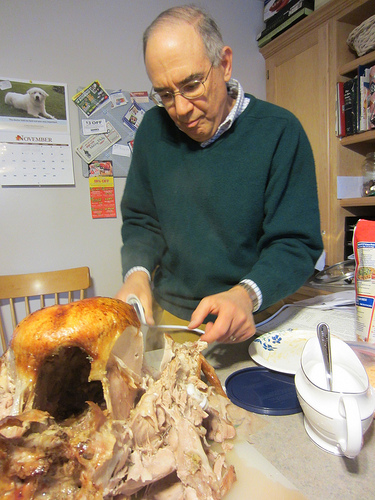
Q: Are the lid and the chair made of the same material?
A: No, the lid is made of plastic and the chair is made of wood.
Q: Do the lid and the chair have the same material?
A: No, the lid is made of plastic and the chair is made of wood.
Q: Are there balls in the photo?
A: No, there are no balls.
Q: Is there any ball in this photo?
A: No, there are no balls.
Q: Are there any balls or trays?
A: No, there are no balls or trays.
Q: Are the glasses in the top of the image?
A: Yes, the glasses are in the top of the image.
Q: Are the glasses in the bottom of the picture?
A: No, the glasses are in the top of the image.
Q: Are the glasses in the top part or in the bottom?
A: The glasses are in the top of the image.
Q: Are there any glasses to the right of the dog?
A: Yes, there are glasses to the right of the dog.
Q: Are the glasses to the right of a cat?
A: No, the glasses are to the right of the dog.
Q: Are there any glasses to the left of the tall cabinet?
A: Yes, there are glasses to the left of the cabinet.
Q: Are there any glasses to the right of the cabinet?
A: No, the glasses are to the left of the cabinet.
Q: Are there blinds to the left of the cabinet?
A: No, there are glasses to the left of the cabinet.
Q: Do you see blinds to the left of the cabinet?
A: No, there are glasses to the left of the cabinet.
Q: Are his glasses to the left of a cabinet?
A: Yes, the glasses are to the left of a cabinet.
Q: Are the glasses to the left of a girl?
A: No, the glasses are to the left of a cabinet.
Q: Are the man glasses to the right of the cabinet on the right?
A: No, the glasses are to the left of the cabinet.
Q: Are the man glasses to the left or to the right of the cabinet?
A: The glasses are to the left of the cabinet.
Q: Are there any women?
A: No, there are no women.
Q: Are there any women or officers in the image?
A: No, there are no women or officers.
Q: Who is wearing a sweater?
A: The man is wearing a sweater.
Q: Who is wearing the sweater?
A: The man is wearing a sweater.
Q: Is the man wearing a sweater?
A: Yes, the man is wearing a sweater.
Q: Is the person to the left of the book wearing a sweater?
A: Yes, the man is wearing a sweater.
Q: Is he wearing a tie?
A: No, the man is wearing a sweater.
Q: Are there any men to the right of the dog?
A: Yes, there is a man to the right of the dog.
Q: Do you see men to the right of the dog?
A: Yes, there is a man to the right of the dog.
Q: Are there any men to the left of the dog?
A: No, the man is to the right of the dog.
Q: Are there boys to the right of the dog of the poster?
A: No, there is a man to the right of the dog.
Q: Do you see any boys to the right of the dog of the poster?
A: No, there is a man to the right of the dog.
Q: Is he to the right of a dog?
A: Yes, the man is to the right of a dog.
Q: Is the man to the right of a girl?
A: No, the man is to the right of a dog.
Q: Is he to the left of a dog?
A: No, the man is to the right of a dog.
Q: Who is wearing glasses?
A: The man is wearing glasses.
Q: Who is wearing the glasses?
A: The man is wearing glasses.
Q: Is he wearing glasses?
A: Yes, the man is wearing glasses.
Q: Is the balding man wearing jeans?
A: No, the man is wearing glasses.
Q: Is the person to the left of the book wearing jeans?
A: No, the man is wearing glasses.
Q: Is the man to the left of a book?
A: Yes, the man is to the left of a book.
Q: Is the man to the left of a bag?
A: No, the man is to the left of a book.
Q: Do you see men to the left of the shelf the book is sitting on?
A: Yes, there is a man to the left of the shelf.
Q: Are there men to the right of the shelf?
A: No, the man is to the left of the shelf.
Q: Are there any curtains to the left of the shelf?
A: No, there is a man to the left of the shelf.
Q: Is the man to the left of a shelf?
A: Yes, the man is to the left of a shelf.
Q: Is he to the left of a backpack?
A: No, the man is to the left of a shelf.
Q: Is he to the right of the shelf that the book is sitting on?
A: No, the man is to the left of the shelf.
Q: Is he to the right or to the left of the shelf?
A: The man is to the left of the shelf.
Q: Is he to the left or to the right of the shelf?
A: The man is to the left of the shelf.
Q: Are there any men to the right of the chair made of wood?
A: Yes, there is a man to the right of the chair.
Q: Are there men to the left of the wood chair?
A: No, the man is to the right of the chair.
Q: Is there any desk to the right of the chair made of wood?
A: No, there is a man to the right of the chair.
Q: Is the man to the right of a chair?
A: Yes, the man is to the right of a chair.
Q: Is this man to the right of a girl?
A: No, the man is to the right of a chair.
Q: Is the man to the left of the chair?
A: No, the man is to the right of the chair.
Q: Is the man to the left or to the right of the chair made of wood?
A: The man is to the right of the chair.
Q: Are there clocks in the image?
A: No, there are no clocks.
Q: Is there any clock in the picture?
A: No, there are no clocks.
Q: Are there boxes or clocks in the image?
A: No, there are no clocks or boxes.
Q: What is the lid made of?
A: The lid is made of plastic.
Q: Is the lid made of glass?
A: No, the lid is made of plastic.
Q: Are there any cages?
A: No, there are no cages.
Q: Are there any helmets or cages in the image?
A: No, there are no cages or helmets.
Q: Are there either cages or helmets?
A: No, there are no cages or helmets.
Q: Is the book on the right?
A: Yes, the book is on the right of the image.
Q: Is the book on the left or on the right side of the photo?
A: The book is on the right of the image.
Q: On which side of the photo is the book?
A: The book is on the right of the image.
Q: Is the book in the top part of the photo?
A: Yes, the book is in the top of the image.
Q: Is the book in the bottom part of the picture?
A: No, the book is in the top of the image.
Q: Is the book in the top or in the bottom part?
A: The book is in the top of the image.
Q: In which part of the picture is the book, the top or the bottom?
A: The book is in the top of the image.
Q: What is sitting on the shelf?
A: The book is sitting on the shelf.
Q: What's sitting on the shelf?
A: The book is sitting on the shelf.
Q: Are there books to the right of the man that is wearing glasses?
A: Yes, there is a book to the right of the man.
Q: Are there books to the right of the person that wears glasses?
A: Yes, there is a book to the right of the man.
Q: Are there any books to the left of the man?
A: No, the book is to the right of the man.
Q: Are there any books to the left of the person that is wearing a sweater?
A: No, the book is to the right of the man.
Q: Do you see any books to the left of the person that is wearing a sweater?
A: No, the book is to the right of the man.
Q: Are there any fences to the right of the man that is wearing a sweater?
A: No, there is a book to the right of the man.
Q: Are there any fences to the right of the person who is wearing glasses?
A: No, there is a book to the right of the man.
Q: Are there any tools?
A: No, there are no tools.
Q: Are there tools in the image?
A: No, there are no tools.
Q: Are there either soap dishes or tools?
A: No, there are no tools or soap dishes.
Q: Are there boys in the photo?
A: No, there are no boys.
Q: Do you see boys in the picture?
A: No, there are no boys.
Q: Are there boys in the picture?
A: No, there are no boys.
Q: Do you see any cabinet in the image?
A: Yes, there is a cabinet.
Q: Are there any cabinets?
A: Yes, there is a cabinet.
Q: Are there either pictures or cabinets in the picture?
A: Yes, there is a cabinet.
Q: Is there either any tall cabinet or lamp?
A: Yes, there is a tall cabinet.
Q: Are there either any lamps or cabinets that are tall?
A: Yes, the cabinet is tall.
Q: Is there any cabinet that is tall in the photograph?
A: Yes, there is a tall cabinet.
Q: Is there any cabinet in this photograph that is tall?
A: Yes, there is a cabinet that is tall.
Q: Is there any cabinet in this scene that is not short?
A: Yes, there is a tall cabinet.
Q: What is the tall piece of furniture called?
A: The piece of furniture is a cabinet.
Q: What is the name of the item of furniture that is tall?
A: The piece of furniture is a cabinet.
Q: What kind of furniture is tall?
A: The furniture is a cabinet.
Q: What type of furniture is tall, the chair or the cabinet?
A: The cabinet is tall.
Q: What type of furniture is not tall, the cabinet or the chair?
A: The chair is not tall.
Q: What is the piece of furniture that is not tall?
A: The piece of furniture is a chair.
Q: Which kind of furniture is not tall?
A: The furniture is a chair.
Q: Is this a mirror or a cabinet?
A: This is a cabinet.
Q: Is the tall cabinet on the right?
A: Yes, the cabinet is on the right of the image.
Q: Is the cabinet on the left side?
A: No, the cabinet is on the right of the image.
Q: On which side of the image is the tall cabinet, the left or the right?
A: The cabinet is on the right of the image.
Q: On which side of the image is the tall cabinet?
A: The cabinet is on the right of the image.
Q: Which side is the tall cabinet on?
A: The cabinet is on the right of the image.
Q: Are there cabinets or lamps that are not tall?
A: No, there is a cabinet but it is tall.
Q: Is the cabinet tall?
A: Yes, the cabinet is tall.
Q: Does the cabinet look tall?
A: Yes, the cabinet is tall.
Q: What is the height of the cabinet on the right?
A: The cabinet is tall.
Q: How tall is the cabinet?
A: The cabinet is tall.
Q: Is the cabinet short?
A: No, the cabinet is tall.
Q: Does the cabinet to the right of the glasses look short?
A: No, the cabinet is tall.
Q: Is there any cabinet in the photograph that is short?
A: No, there is a cabinet but it is tall.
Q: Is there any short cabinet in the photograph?
A: No, there is a cabinet but it is tall.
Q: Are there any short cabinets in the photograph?
A: No, there is a cabinet but it is tall.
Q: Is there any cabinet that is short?
A: No, there is a cabinet but it is tall.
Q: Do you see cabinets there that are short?
A: No, there is a cabinet but it is tall.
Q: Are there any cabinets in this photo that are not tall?
A: No, there is a cabinet but it is tall.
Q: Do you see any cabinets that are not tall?
A: No, there is a cabinet but it is tall.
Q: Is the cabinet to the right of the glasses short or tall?
A: The cabinet is tall.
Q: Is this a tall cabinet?
A: Yes, this is a tall cabinet.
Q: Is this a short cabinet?
A: No, this is a tall cabinet.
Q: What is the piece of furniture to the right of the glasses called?
A: The piece of furniture is a cabinet.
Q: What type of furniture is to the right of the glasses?
A: The piece of furniture is a cabinet.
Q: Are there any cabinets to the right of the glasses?
A: Yes, there is a cabinet to the right of the glasses.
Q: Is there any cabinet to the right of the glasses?
A: Yes, there is a cabinet to the right of the glasses.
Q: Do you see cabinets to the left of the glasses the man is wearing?
A: No, the cabinet is to the right of the glasses.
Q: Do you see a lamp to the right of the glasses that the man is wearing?
A: No, there is a cabinet to the right of the glasses.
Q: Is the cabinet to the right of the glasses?
A: Yes, the cabinet is to the right of the glasses.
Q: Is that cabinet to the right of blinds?
A: No, the cabinet is to the right of the glasses.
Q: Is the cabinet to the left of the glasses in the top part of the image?
A: No, the cabinet is to the right of the glasses.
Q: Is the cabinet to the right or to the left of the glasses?
A: The cabinet is to the right of the glasses.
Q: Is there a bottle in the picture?
A: No, there are no bottles.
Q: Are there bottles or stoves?
A: No, there are no bottles or stoves.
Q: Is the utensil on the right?
A: Yes, the utensil is on the right of the image.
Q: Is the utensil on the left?
A: No, the utensil is on the right of the image.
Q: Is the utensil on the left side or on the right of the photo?
A: The utensil is on the right of the image.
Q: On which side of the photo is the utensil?
A: The utensil is on the right of the image.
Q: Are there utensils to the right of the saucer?
A: Yes, there is a utensil to the right of the saucer.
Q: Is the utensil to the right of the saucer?
A: Yes, the utensil is to the right of the saucer.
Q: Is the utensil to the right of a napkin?
A: No, the utensil is to the right of the saucer.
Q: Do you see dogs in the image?
A: Yes, there is a dog.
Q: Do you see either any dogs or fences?
A: Yes, there is a dog.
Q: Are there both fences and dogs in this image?
A: No, there is a dog but no fences.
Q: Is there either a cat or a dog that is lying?
A: Yes, the dog is lying.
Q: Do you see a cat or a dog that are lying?
A: Yes, the dog is lying.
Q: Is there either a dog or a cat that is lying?
A: Yes, the dog is lying.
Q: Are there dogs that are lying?
A: Yes, there is a dog that is lying.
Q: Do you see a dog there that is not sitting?
A: Yes, there is a dog that is lying .